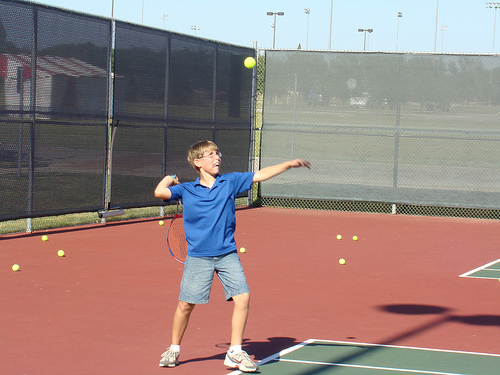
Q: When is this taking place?
A: Daytime.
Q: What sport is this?
A: Tennis.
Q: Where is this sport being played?
A: Tennis court.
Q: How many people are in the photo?
A: One.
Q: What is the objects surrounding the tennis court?
A: Fence.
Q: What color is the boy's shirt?
A: Blue.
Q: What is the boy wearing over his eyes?
A: Eye glasses.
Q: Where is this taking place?
A: On the tennis court.